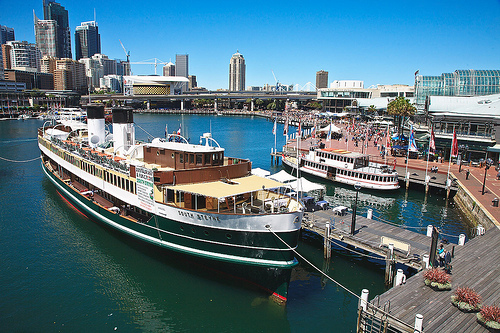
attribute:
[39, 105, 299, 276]
boat — big, tied, large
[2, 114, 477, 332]
water — blue green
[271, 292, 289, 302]
stripe — red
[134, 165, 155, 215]
poster — announcing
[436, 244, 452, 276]
people — tiny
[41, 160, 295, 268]
stripe — green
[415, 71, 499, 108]
building — rounded, glass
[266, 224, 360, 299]
cable — attaching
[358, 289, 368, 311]
post — white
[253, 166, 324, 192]
tarp — white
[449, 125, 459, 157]
flag — drooping, red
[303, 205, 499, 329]
dock — wooden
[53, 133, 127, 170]
decoration — flowery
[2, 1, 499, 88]
sky — blue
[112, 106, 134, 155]
pillar — large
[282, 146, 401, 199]
boat — small